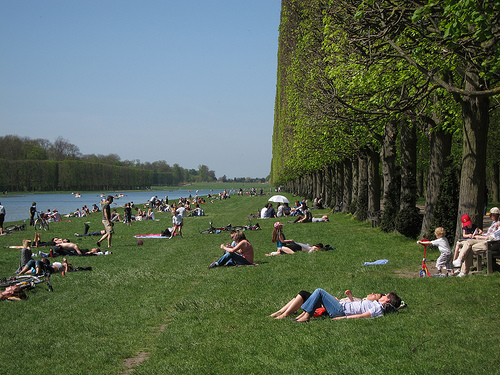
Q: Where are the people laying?
A: Grass.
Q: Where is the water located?
A: In front.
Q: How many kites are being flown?
A: None.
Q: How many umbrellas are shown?
A: One.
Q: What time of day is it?
A: Daytime.